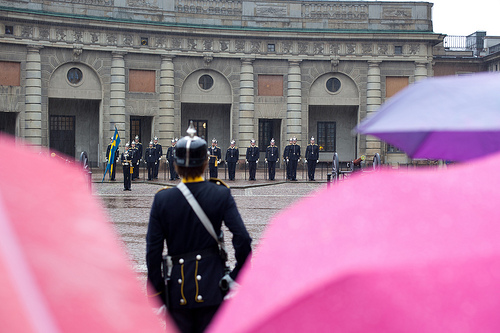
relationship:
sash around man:
[176, 182, 218, 243] [145, 135, 251, 332]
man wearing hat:
[145, 135, 251, 332] [168, 122, 208, 169]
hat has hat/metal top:
[173, 137, 211, 167] [186, 120, 197, 136]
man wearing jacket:
[145, 135, 251, 332] [142, 180, 252, 310]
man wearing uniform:
[145, 135, 251, 332] [144, 120, 249, 290]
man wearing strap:
[145, 135, 251, 332] [178, 185, 215, 242]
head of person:
[143, 122, 227, 186] [146, 120, 253, 292]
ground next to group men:
[98, 180, 319, 225] [106, 134, 322, 189]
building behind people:
[2, 1, 446, 166] [114, 131, 324, 183]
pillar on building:
[25, 54, 431, 162] [2, 1, 446, 166]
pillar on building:
[159, 62, 175, 143] [2, 1, 446, 166]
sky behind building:
[435, 5, 498, 32] [2, 1, 446, 166]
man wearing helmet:
[142, 180, 252, 307] [162, 119, 212, 181]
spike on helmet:
[186, 122, 193, 132] [174, 133, 210, 176]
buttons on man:
[175, 255, 204, 305] [101, 147, 278, 292]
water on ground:
[96, 190, 154, 213] [92, 172, 359, 318]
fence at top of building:
[444, 30, 498, 51] [5, 3, 497, 174]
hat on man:
[173, 121, 208, 167] [144, 119, 253, 331]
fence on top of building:
[440, 30, 494, 53] [5, 3, 497, 174]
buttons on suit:
[178, 255, 203, 303] [147, 181, 252, 319]